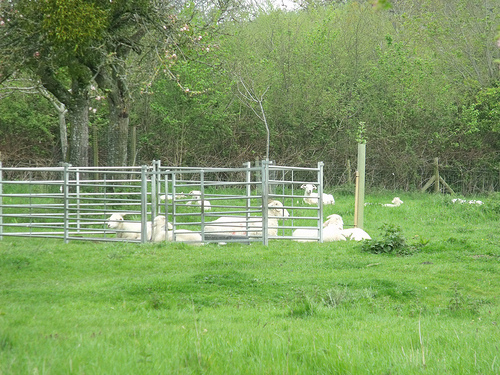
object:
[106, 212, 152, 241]
white sheep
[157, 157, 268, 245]
metal gate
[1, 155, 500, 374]
sheep enclosure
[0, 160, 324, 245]
fence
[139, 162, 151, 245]
pole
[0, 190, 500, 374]
ground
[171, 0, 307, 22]
sky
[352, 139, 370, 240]
fence pole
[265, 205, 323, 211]
fence pole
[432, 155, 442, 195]
poles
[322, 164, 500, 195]
fence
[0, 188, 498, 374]
field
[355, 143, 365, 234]
metal pole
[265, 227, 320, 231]
pole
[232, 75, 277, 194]
tree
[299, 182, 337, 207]
goats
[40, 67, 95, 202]
trunk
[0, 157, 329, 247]
pen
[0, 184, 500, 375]
grass